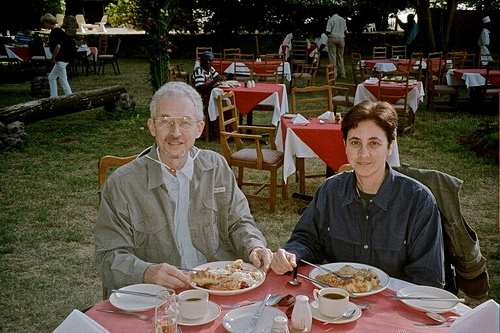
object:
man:
[94, 81, 273, 299]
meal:
[186, 258, 266, 294]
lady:
[269, 101, 445, 288]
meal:
[309, 262, 390, 297]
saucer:
[165, 300, 221, 326]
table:
[84, 263, 473, 332]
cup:
[170, 289, 208, 321]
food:
[190, 259, 261, 290]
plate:
[188, 259, 266, 295]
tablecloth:
[52, 263, 499, 331]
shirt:
[282, 161, 446, 290]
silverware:
[299, 257, 355, 280]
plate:
[309, 262, 390, 297]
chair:
[216, 90, 288, 211]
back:
[217, 90, 245, 159]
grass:
[0, 57, 499, 332]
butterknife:
[296, 272, 357, 298]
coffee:
[323, 292, 345, 299]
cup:
[313, 287, 350, 318]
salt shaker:
[290, 295, 312, 333]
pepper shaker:
[271, 316, 289, 332]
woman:
[40, 13, 71, 96]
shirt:
[48, 26, 70, 61]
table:
[275, 115, 397, 206]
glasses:
[149, 116, 199, 129]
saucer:
[309, 299, 362, 325]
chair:
[291, 85, 334, 195]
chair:
[98, 155, 137, 303]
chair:
[378, 71, 416, 136]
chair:
[290, 51, 321, 89]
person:
[477, 15, 494, 66]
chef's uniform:
[477, 15, 495, 66]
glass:
[154, 289, 180, 332]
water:
[156, 315, 176, 332]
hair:
[148, 82, 205, 123]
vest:
[389, 162, 490, 300]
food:
[315, 264, 380, 291]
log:
[1, 85, 137, 133]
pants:
[48, 61, 71, 98]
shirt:
[96, 146, 267, 294]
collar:
[156, 145, 194, 179]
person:
[190, 50, 233, 140]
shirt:
[191, 65, 219, 87]